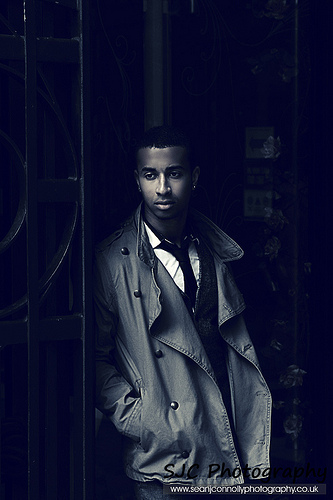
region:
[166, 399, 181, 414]
button on the mans jacket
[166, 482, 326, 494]
photography website for the company that took the photo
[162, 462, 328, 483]
photographer logo and name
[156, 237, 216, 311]
black tie the man is wearing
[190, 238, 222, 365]
a vest that is under the coat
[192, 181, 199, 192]
earring in the mans ear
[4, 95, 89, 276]
an iron gate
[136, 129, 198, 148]
the mans black hair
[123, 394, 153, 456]
the pocket on the coat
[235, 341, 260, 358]
a button hole on the coat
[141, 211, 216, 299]
a man wearing a necktie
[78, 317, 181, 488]
man's hand in the pocket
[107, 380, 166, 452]
man's hand in the pocket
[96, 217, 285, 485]
man is wearing a jacket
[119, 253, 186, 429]
the jacket has buttons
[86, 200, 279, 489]
Man wearing a coat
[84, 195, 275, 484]
Man is wearing a coat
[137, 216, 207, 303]
Man wearing a shirt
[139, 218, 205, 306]
Man is wearing a shirt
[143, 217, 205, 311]
Man wearing a white shirt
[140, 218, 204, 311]
Man is wearing a white shirt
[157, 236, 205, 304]
Man wearing a tie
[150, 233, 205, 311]
Man is wearing a tie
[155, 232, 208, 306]
Man wearing a black tie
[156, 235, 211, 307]
Man is wearing a black tie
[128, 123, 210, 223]
The head of a young adult black male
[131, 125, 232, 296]
A young adult black make dressed in a vest, tie, and outdoor coat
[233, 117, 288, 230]
Reflection of signs on a glass door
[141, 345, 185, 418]
A couple of buttons on an overcoat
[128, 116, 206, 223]
A young adult make with his ears pierced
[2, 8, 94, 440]
Robust decorative iron gating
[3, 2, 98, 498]
Some decorative iron gating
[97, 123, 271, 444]
A young adult professional male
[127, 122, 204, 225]
A young adult male with a prominent nose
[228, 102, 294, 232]
Street sign reflections on glass